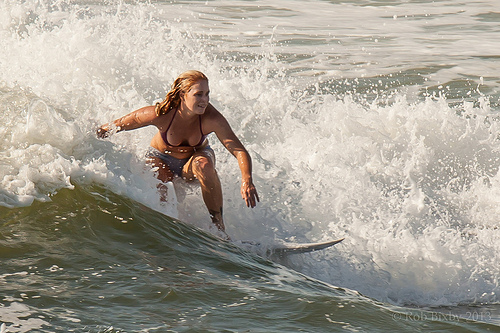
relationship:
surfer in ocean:
[76, 47, 270, 238] [287, 97, 498, 280]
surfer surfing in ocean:
[94, 68, 260, 232] [4, 5, 496, 332]